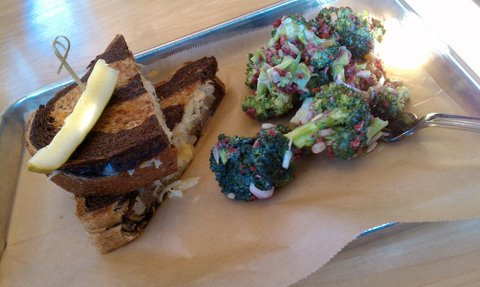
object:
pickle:
[24, 57, 121, 196]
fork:
[358, 113, 479, 141]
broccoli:
[208, 127, 299, 201]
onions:
[246, 183, 278, 200]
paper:
[0, 0, 478, 284]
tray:
[0, 1, 480, 287]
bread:
[21, 34, 228, 258]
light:
[373, 11, 457, 73]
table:
[0, 0, 290, 108]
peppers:
[271, 43, 299, 68]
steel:
[384, 110, 480, 144]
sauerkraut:
[162, 112, 202, 145]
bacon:
[257, 46, 297, 60]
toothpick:
[48, 34, 100, 98]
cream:
[373, 18, 436, 71]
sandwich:
[25, 31, 230, 252]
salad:
[231, 0, 414, 159]